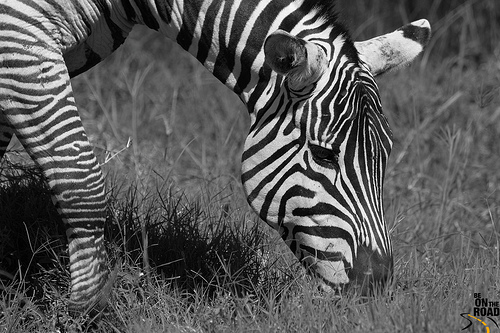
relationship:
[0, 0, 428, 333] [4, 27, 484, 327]
zebra eating grass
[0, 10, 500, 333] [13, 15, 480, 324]
grass in ground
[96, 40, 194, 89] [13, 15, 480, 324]
grass in ground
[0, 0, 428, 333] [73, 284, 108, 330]
zebra has feet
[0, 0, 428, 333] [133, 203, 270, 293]
zebra has shadow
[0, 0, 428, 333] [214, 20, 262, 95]
zebra has a neck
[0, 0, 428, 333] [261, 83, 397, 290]
zebra has a head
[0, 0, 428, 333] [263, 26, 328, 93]
zebra has an ear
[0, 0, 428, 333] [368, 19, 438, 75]
zebra has an ear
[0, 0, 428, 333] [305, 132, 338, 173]
zebra has an eye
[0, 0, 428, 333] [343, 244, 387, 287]
zebra has a nose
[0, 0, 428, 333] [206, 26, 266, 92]
zebra has a neck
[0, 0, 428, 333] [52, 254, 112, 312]
zebra has feet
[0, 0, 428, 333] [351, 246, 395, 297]
zebra has a nose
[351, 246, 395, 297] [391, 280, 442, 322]
nose in grass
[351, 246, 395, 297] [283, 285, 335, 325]
nose in grass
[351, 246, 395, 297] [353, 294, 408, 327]
nose in grass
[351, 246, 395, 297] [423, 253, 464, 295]
nose in grass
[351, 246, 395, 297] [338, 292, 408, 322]
nose in grass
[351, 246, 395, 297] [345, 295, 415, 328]
nose in grass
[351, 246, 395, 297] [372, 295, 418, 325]
nose in grass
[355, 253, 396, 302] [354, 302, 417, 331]
nose in grass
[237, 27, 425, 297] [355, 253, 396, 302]
zebra has a nose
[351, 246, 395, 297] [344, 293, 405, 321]
nose in grass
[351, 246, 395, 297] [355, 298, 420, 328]
nose in grass